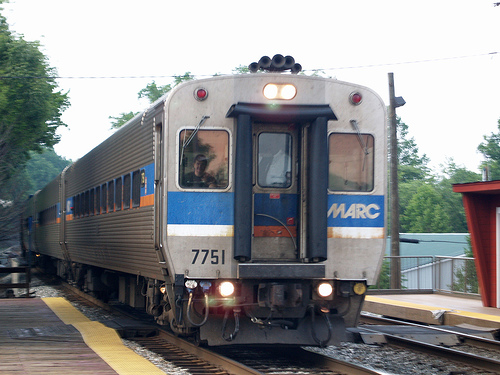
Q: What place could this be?
A: It is a station.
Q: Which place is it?
A: It is a station.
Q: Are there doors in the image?
A: Yes, there is a door.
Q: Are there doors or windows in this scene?
A: Yes, there is a door.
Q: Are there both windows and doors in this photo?
A: Yes, there are both a door and a window.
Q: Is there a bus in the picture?
A: No, there are no buses.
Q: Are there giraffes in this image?
A: No, there are no giraffes.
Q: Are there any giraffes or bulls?
A: No, there are no giraffes or bulls.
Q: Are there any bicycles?
A: No, there are no bicycles.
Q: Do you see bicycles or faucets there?
A: No, there are no bicycles or faucets.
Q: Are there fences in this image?
A: Yes, there is a fence.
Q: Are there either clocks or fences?
A: Yes, there is a fence.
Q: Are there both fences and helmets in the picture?
A: No, there is a fence but no helmets.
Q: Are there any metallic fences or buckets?
A: Yes, there is a metal fence.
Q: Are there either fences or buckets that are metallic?
A: Yes, the fence is metallic.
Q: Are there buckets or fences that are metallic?
A: Yes, the fence is metallic.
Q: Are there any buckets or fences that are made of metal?
A: Yes, the fence is made of metal.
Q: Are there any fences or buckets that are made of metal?
A: Yes, the fence is made of metal.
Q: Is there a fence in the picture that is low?
A: Yes, there is a low fence.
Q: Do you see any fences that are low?
A: Yes, there is a low fence.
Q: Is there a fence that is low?
A: Yes, there is a fence that is low.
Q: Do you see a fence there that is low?
A: Yes, there is a fence that is low.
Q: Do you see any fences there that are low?
A: Yes, there is a fence that is low.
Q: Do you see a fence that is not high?
A: Yes, there is a low fence.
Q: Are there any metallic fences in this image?
A: Yes, there is a metal fence.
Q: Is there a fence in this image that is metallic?
A: Yes, there is a fence that is metallic.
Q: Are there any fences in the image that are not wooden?
A: Yes, there is a metallic fence.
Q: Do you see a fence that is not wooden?
A: Yes, there is a metallic fence.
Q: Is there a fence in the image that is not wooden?
A: Yes, there is a metallic fence.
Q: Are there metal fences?
A: Yes, there is a fence that is made of metal.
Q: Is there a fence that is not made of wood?
A: Yes, there is a fence that is made of metal.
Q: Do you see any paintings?
A: No, there are no paintings.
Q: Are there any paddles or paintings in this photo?
A: No, there are no paintings or paddles.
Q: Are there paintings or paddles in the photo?
A: No, there are no paintings or paddles.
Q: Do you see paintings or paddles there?
A: No, there are no paintings or paddles.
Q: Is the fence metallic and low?
A: Yes, the fence is metallic and low.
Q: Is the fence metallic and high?
A: No, the fence is metallic but low.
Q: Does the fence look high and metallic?
A: No, the fence is metallic but low.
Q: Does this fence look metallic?
A: Yes, the fence is metallic.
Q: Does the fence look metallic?
A: Yes, the fence is metallic.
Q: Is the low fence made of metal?
A: Yes, the fence is made of metal.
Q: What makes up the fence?
A: The fence is made of metal.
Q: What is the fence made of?
A: The fence is made of metal.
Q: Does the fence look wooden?
A: No, the fence is metallic.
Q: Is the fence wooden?
A: No, the fence is metallic.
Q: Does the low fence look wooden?
A: No, the fence is metallic.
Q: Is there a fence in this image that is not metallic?
A: No, there is a fence but it is metallic.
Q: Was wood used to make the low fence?
A: No, the fence is made of metal.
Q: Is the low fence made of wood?
A: No, the fence is made of metal.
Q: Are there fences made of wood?
A: No, there is a fence but it is made of metal.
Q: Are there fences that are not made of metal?
A: No, there is a fence but it is made of metal.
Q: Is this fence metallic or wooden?
A: The fence is metallic.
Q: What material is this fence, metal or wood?
A: The fence is made of metal.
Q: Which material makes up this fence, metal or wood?
A: The fence is made of metal.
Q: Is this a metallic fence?
A: Yes, this is a metallic fence.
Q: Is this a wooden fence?
A: No, this is a metallic fence.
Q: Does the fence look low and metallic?
A: Yes, the fence is low and metallic.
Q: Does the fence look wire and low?
A: No, the fence is low but metallic.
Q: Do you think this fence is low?
A: Yes, the fence is low.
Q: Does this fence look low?
A: Yes, the fence is low.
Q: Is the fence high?
A: No, the fence is low.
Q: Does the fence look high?
A: No, the fence is low.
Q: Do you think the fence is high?
A: No, the fence is low.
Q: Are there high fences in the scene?
A: No, there is a fence but it is low.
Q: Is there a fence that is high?
A: No, there is a fence but it is low.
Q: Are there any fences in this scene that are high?
A: No, there is a fence but it is low.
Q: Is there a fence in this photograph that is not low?
A: No, there is a fence but it is low.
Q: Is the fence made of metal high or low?
A: The fence is low.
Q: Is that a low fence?
A: Yes, that is a low fence.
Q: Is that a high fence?
A: No, that is a low fence.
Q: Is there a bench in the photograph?
A: No, there are no benches.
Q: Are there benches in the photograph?
A: No, there are no benches.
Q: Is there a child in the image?
A: No, there are no children.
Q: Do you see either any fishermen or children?
A: No, there are no children or fishermen.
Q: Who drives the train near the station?
A: The man drives the train.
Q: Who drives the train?
A: The man drives the train.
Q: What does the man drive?
A: The man drives the train.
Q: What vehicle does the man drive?
A: The man drives the train.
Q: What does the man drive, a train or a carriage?
A: The man drives a train.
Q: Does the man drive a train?
A: Yes, the man drives a train.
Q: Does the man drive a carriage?
A: No, the man drives a train.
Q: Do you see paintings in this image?
A: No, there are no paintings.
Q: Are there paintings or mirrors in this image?
A: No, there are no paintings or mirrors.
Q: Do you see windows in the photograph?
A: Yes, there are windows.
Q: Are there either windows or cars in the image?
A: Yes, there are windows.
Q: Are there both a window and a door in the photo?
A: Yes, there are both a window and a door.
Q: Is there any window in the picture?
A: Yes, there is a window.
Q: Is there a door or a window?
A: Yes, there is a window.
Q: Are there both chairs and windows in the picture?
A: No, there is a window but no chairs.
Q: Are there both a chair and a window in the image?
A: No, there is a window but no chairs.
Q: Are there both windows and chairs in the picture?
A: No, there is a window but no chairs.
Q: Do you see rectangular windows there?
A: Yes, there is a rectangular window.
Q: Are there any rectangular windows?
A: Yes, there is a rectangular window.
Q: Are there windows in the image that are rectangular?
A: Yes, there is a window that is rectangular.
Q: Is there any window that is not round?
A: Yes, there is a rectangular window.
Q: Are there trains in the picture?
A: Yes, there is a train.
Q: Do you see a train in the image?
A: Yes, there is a train.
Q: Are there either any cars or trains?
A: Yes, there is a train.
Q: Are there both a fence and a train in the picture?
A: Yes, there are both a train and a fence.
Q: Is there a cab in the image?
A: No, there are no taxis.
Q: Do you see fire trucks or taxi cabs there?
A: No, there are no taxi cabs or fire trucks.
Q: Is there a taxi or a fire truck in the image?
A: No, there are no taxis or fire trucks.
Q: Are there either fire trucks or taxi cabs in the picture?
A: No, there are no taxi cabs or fire trucks.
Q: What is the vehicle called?
A: The vehicle is a train.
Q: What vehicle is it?
A: The vehicle is a train.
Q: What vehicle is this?
A: This is a train.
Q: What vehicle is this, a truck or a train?
A: This is a train.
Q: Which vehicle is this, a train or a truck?
A: This is a train.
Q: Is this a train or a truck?
A: This is a train.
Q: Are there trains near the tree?
A: Yes, there is a train near the tree.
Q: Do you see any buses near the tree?
A: No, there is a train near the tree.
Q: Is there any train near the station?
A: Yes, there is a train near the station.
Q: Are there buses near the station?
A: No, there is a train near the station.